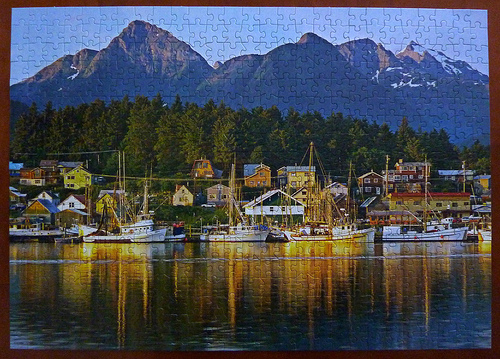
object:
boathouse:
[242, 189, 307, 228]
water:
[14, 313, 40, 341]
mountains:
[9, 19, 491, 148]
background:
[11, 7, 489, 241]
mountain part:
[299, 65, 320, 88]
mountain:
[9, 47, 98, 87]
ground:
[187, 214, 191, 216]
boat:
[9, 223, 64, 242]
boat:
[83, 219, 187, 243]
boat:
[200, 223, 271, 242]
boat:
[281, 224, 374, 242]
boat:
[382, 217, 469, 241]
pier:
[35, 183, 483, 227]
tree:
[123, 103, 153, 177]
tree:
[153, 110, 185, 174]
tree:
[202, 104, 247, 168]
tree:
[265, 120, 299, 165]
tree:
[45, 107, 70, 161]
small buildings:
[438, 170, 474, 181]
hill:
[196, 32, 391, 112]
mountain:
[394, 40, 488, 91]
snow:
[412, 45, 462, 75]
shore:
[139, 190, 381, 233]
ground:
[208, 212, 211, 213]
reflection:
[7, 240, 491, 350]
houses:
[357, 169, 385, 195]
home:
[244, 162, 272, 188]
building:
[187, 155, 223, 179]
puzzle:
[7, 6, 494, 353]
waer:
[16, 244, 482, 344]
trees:
[426, 128, 451, 168]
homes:
[277, 162, 317, 198]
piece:
[415, 19, 442, 47]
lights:
[116, 243, 148, 342]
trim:
[242, 187, 307, 227]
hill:
[7, 93, 491, 233]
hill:
[83, 20, 215, 88]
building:
[64, 165, 94, 191]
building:
[19, 160, 84, 187]